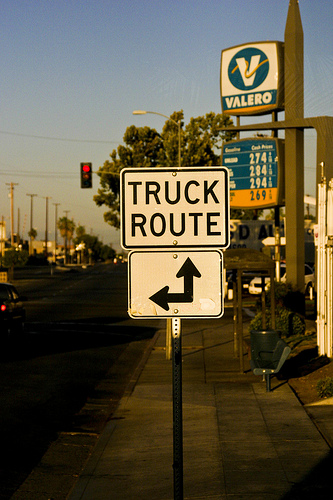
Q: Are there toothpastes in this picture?
A: No, there are no toothpastes.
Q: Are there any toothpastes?
A: No, there are no toothpastes.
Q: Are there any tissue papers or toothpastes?
A: No, there are no toothpastes or tissue papers.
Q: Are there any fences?
A: No, there are no fences.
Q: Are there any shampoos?
A: No, there are no shampoos.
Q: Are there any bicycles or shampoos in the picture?
A: No, there are no shampoos or bicycles.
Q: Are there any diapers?
A: No, there are no diapers.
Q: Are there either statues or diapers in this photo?
A: No, there are no diapers or statues.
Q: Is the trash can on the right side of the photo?
A: Yes, the trash can is on the right of the image.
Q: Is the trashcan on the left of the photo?
A: No, the trashcan is on the right of the image.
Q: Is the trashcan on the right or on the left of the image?
A: The trashcan is on the right of the image.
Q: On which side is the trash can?
A: The trash can is on the right of the image.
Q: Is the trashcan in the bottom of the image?
A: Yes, the trashcan is in the bottom of the image.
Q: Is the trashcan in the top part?
A: No, the trashcan is in the bottom of the image.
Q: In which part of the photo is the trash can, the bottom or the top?
A: The trash can is in the bottom of the image.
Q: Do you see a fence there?
A: No, there are no fences.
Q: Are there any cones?
A: No, there are no cones.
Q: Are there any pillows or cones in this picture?
A: No, there are no cones or pillows.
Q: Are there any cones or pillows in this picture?
A: No, there are no cones or pillows.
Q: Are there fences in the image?
A: No, there are no fences.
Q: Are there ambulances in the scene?
A: No, there are no ambulances.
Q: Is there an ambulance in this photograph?
A: No, there are no ambulances.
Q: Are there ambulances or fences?
A: No, there are no ambulances or fences.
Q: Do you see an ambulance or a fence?
A: No, there are no ambulances or fences.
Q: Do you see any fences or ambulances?
A: No, there are no ambulances or fences.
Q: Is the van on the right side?
A: Yes, the van is on the right of the image.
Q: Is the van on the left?
A: No, the van is on the right of the image.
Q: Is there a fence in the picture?
A: No, there are no fences.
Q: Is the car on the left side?
A: Yes, the car is on the left of the image.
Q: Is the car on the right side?
A: No, the car is on the left of the image.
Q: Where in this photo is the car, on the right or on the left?
A: The car is on the left of the image.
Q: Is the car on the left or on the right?
A: The car is on the left of the image.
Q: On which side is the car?
A: The car is on the left of the image.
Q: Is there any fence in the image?
A: No, there are no fences.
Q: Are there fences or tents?
A: No, there are no fences or tents.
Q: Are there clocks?
A: No, there are no clocks.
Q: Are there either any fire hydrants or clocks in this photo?
A: No, there are no clocks or fire hydrants.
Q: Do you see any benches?
A: Yes, there is a bench.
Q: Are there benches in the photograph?
A: Yes, there is a bench.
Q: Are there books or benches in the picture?
A: Yes, there is a bench.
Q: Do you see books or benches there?
A: Yes, there is a bench.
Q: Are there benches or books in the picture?
A: Yes, there is a bench.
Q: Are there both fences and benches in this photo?
A: No, there is a bench but no fences.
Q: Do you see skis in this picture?
A: No, there are no skis.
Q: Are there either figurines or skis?
A: No, there are no skis or figurines.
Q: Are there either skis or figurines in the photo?
A: No, there are no skis or figurines.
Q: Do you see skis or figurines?
A: No, there are no skis or figurines.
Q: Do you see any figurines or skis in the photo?
A: No, there are no skis or figurines.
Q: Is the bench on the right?
A: Yes, the bench is on the right of the image.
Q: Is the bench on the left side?
A: No, the bench is on the right of the image.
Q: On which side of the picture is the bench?
A: The bench is on the right of the image.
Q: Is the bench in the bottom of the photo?
A: Yes, the bench is in the bottom of the image.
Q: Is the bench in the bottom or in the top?
A: The bench is in the bottom of the image.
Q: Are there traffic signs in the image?
A: Yes, there is a traffic sign.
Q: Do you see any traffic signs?
A: Yes, there is a traffic sign.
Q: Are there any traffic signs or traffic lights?
A: Yes, there is a traffic sign.